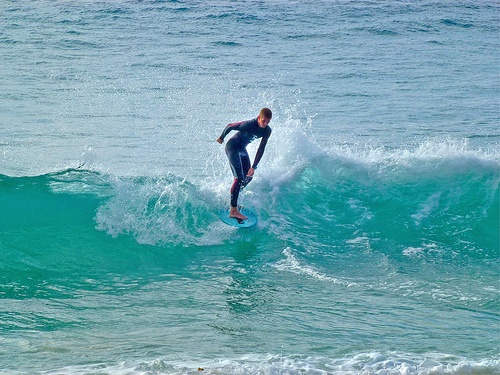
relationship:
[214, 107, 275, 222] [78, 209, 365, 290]
man in water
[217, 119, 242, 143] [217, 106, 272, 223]
arm of person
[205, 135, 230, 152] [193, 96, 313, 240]
hand of person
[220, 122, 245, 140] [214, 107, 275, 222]
arm of man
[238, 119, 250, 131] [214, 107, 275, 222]
shoulder of man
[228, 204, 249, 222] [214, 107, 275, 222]
feet of man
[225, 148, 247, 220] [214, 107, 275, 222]
leg of man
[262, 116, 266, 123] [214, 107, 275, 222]
eye of man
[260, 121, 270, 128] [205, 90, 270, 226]
nose of person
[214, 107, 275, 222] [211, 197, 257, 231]
man on board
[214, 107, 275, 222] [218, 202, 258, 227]
man on board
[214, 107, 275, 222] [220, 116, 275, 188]
man wearing wet suit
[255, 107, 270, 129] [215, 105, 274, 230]
head of person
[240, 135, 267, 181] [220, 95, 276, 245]
arm of person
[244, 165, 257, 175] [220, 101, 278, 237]
hand of person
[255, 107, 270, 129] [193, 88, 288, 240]
head of man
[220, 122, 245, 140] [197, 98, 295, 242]
arm of man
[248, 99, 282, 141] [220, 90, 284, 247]
head of person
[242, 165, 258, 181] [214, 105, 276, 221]
hand of person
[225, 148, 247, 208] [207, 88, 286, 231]
leg of person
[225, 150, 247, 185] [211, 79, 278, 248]
thigh of person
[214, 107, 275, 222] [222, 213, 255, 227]
man on a surfboard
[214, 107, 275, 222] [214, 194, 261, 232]
man on a board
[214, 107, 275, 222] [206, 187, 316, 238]
man on a surfboard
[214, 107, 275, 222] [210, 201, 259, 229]
man on a board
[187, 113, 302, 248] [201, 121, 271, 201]
man wearing wet suit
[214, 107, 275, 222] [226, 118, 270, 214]
man wearing wetsuit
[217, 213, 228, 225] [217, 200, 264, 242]
edge of a surfboard